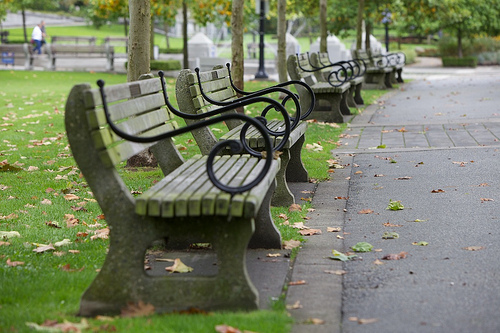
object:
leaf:
[31, 239, 54, 254]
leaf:
[296, 227, 320, 237]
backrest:
[82, 75, 176, 167]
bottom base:
[77, 214, 260, 312]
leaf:
[382, 250, 407, 260]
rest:
[249, 178, 281, 249]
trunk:
[127, 0, 161, 158]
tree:
[204, 1, 261, 108]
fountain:
[188, 32, 214, 58]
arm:
[94, 81, 272, 193]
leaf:
[386, 200, 406, 211]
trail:
[283, 67, 500, 331]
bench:
[287, 52, 352, 123]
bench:
[176, 63, 315, 207]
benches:
[63, 71, 292, 314]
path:
[0, 57, 473, 81]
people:
[32, 23, 44, 54]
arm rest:
[226, 64, 317, 120]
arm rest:
[291, 55, 347, 85]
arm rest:
[157, 71, 292, 158]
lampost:
[380, 10, 392, 51]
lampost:
[256, 0, 268, 77]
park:
[2, 0, 499, 332]